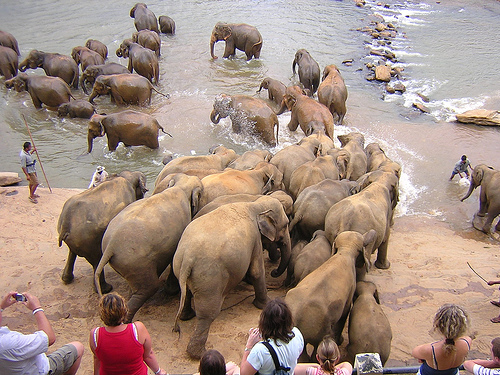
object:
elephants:
[284, 229, 332, 289]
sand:
[398, 241, 450, 295]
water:
[393, 133, 441, 159]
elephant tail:
[170, 248, 194, 333]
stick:
[22, 113, 52, 193]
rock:
[375, 65, 391, 82]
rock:
[393, 84, 406, 95]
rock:
[390, 67, 404, 78]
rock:
[417, 93, 430, 103]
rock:
[366, 77, 375, 80]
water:
[444, 47, 500, 82]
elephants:
[87, 110, 173, 154]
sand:
[7, 216, 50, 269]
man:
[0, 291, 83, 374]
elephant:
[172, 195, 291, 359]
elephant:
[283, 239, 308, 287]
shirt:
[246, 326, 304, 375]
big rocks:
[356, 0, 432, 120]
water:
[434, 15, 500, 56]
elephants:
[210, 21, 263, 61]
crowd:
[0, 291, 499, 375]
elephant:
[209, 21, 264, 59]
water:
[24, 6, 106, 30]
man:
[450, 155, 474, 181]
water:
[397, 110, 437, 134]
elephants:
[460, 164, 500, 233]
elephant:
[256, 77, 287, 106]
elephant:
[155, 146, 241, 187]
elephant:
[94, 173, 204, 324]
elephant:
[57, 100, 97, 119]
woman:
[89, 291, 167, 374]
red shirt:
[92, 323, 154, 375]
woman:
[239, 297, 305, 375]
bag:
[260, 340, 290, 374]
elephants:
[289, 149, 351, 199]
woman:
[412, 304, 473, 375]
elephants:
[344, 280, 392, 367]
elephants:
[199, 162, 283, 212]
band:
[429, 303, 470, 337]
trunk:
[210, 38, 218, 59]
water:
[268, 7, 354, 47]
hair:
[429, 304, 472, 359]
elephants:
[57, 170, 149, 294]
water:
[187, 61, 216, 82]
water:
[418, 191, 451, 208]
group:
[57, 120, 403, 368]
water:
[44, 124, 77, 148]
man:
[20, 142, 41, 204]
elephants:
[288, 178, 358, 236]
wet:
[210, 93, 279, 147]